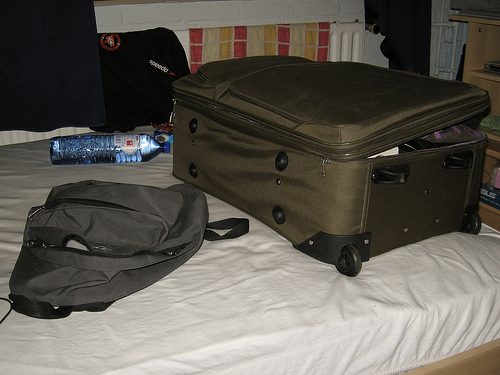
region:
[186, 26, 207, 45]
Red square shape on a bath towel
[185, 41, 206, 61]
Red square shape on a bath towel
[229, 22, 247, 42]
Red square shape on a bath towel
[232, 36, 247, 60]
Red square shape on a bath towel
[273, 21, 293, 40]
Red square shape on a bath towel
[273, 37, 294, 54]
Red square shape on a bath towel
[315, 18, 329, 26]
Red square shape on a bath towel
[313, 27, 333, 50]
Red square shape on a bath towel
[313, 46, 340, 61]
Red square shape on a bath towel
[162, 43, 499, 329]
Green luggage sitting on the bed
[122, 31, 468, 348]
a suitcase on teh bed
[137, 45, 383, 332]
a green suitcase on the bed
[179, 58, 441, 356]
a green open suitcase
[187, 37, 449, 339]
a suitcase that is open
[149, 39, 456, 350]
a suitcase that is green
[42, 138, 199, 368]
a backpack on the bed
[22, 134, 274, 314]
a bed with a backpack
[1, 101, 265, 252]
a bottle of water on the bed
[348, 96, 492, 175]
The suitcase is unzipped.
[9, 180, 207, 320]
A backpack is on the bed.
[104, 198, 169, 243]
The backpack is grey.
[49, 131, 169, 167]
A bottle of water is on the bed.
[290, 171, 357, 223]
The suitcase is green.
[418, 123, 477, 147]
The suitcase contains objects.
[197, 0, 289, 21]
The wall is white.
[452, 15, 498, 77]
A bookcase is next to the bed.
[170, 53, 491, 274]
Luggage being packed.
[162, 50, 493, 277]
Suitcase on the bed.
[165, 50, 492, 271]
The suitcase is green.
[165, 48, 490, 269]
The suitcase is half zippered.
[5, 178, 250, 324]
Grey backup on the bed.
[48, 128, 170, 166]
Bottle of water on the bed.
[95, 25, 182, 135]
Shirt hanging aside.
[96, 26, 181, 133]
The black shirt is a Speedo brand.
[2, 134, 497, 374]
Fitted sheet is white.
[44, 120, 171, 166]
water bottle on bed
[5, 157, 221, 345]
book bag on bed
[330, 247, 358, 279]
wheel on the suitcase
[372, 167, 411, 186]
wheel on the suitcase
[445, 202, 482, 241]
wheel on the suitcase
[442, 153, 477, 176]
wheel on the suitcase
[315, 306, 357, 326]
wrinkle on the sheet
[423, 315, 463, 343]
wrinkle on the sheet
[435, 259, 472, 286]
wrinkle on the sheet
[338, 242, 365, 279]
Wheel of a suitcase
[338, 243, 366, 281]
Black wheel of a suitcase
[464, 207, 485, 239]
Wheel of a suitcase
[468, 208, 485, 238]
Wheel of a suitcase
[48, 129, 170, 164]
blue bottle lying sideways on a white sheet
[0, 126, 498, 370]
white crumpled sheet covering a bed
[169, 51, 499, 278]
brown suitcase with black wheels and trim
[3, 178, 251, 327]
gray backpack with black handles and trim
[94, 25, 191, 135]
black shirt with white letters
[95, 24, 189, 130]
black shirt with red emblem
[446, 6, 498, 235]
small tan wooden shelving unit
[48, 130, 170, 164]
plastic bottle with a blue cap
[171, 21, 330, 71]
red and yellow striped curtain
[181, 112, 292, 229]
black stoppers on a brown suitcase